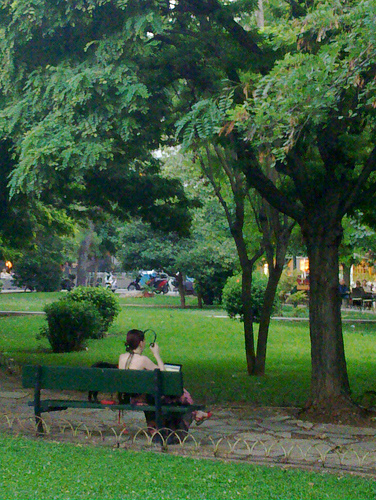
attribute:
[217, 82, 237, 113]
leaves — green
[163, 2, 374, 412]
tree — brown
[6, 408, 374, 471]
fence — short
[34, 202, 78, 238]
leaves — green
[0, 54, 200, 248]
tree — brown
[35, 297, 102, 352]
bush — dark green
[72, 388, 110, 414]
legs — back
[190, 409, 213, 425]
sandals — red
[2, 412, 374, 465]
edging — arched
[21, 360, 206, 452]
bench — park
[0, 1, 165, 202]
leaves — green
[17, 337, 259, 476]
bench — green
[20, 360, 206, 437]
bench — wooden, green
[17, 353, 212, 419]
bench — green, wooden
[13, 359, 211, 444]
bench — green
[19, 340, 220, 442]
bench — green, wooden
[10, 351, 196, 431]
bench — green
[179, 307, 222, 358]
grass — short, green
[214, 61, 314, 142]
leaves — green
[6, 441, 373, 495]
grass — green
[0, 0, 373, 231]
leaves — green, brown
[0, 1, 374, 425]
tree — brown